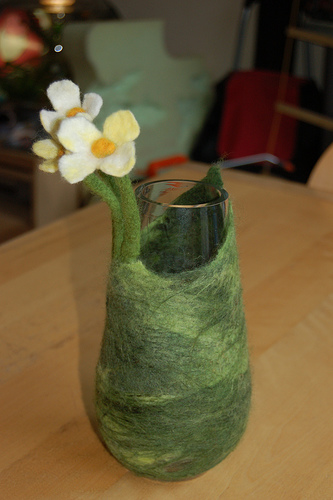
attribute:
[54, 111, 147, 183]
flowers — white, yellow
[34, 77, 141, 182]
fake flower — white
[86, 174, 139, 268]
stem — green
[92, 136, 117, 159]
pistil — fake